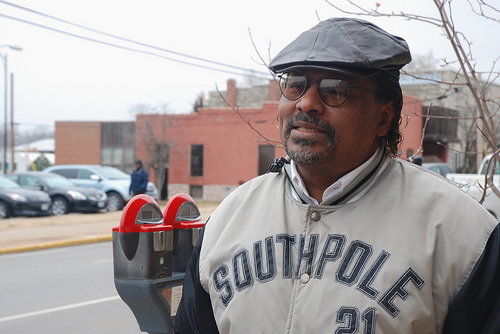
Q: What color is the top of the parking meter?
A: Red.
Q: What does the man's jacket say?
A: Southpole.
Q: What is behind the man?
A: Building.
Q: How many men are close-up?
A: 1.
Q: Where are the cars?
A: Parking lot.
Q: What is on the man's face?
A: Sunglasses.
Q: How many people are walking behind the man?
A: 1.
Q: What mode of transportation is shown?
A: Vehicles.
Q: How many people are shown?
A: 2.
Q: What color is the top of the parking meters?
A: Orange.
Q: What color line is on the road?
A: White.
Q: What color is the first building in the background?
A: Orange.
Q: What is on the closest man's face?
A: Glasses.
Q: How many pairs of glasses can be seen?
A: 1.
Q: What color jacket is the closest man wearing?
A: Gray and black.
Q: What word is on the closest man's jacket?
A: Southpole.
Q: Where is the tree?
A: Behind the man.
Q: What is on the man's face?
A: Glasses.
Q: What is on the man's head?
A: Hat.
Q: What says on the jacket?
A: Southpole.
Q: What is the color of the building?
A: Red.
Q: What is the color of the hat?
A: Black.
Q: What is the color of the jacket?
A: Gray.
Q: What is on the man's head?
A: Hat.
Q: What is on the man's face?
A: Hair.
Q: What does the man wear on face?
A: Glasses.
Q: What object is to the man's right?
A: Parking meters.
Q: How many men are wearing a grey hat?
A: One.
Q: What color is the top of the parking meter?
A: Red.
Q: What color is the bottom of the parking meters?
A: Black.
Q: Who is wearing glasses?
A: Man with grey hat.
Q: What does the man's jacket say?
A: Southpole.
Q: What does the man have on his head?
A: A hat.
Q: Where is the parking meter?
A: To the right of the man.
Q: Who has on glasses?
A: The man near us in the picture.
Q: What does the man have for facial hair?
A: A beard and a mustache.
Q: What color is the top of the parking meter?
A: Red.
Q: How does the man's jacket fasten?
A: With snaps.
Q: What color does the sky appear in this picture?
A: White.